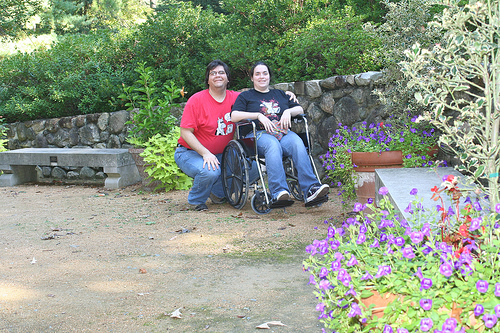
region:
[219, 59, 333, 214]
Woman sitting in a wheelchair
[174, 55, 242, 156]
Woman wearing a red shirt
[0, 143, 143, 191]
A gray stone bench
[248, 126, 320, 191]
A pair of blue jeans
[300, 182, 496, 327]
A bunch of purple flowers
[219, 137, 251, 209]
A round black wheel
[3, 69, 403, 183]
A long stone wall behind the women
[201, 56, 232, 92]
Woman has dark hair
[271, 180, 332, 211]
A pair of sneakers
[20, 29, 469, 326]
this is an outdoor area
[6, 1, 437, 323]
this is in a backyard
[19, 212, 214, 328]
the backyard's ground is dirt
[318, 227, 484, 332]
the flowers are purple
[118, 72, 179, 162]
this is a tall bush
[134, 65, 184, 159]
the tall bush is green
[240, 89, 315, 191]
this person is in a wheelchair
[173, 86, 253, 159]
a person with a red shirt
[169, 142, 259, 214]
a person with blue jeans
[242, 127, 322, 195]
a woman with jeans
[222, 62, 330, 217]
a woman in a wheelchair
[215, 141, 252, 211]
the wheel of a wheelchair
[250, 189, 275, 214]
the wheel of a wheelchair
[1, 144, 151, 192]
a concrete bench near a plant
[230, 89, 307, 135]
a woman with a black shirt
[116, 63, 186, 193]
a pot with green plants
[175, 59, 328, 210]
Two women sit together.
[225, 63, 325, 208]
The woman is in a wheelchair.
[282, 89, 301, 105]
The woman's hand is on the other woman's shoulder.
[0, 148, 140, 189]
The bench is made of stone.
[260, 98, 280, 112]
A graphic is on the shirt.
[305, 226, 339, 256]
The flowers are purple.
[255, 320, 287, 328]
A leaf is on the ground.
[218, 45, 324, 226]
Lady in a wheelchair in a garden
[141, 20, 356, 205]
Man with his arm around a woman in a wheelchair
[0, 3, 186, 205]
Concrete bench in a garden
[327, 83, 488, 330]
Little flowers in a garden near a bench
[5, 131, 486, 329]
Dirt and gravel in a garden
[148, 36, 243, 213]
Man with a red t-shirt and blue jeans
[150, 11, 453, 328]
Two friends in a garden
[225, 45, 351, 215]
Woman sitting in a wheelchair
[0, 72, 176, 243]
Rock wall in a garden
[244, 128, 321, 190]
the jeans are blue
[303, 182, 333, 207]
the shoe is black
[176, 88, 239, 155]
the shirt is red in color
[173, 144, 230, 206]
jeans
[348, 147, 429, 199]
A brown brick colored ceramic pot with a plant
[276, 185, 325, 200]
A pair of black and white shoes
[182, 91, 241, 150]
A red short sleeve shirt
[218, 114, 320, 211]
A metal framed wheel chair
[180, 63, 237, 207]
A person squatting down beside wheel chair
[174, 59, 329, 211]
People in a flower garden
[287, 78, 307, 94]
a stone in a wall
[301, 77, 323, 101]
a stone in a wall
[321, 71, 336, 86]
a stone in a wall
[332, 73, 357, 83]
a stone in a wall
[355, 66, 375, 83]
a stone in a wall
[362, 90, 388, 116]
a stone in a wall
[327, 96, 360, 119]
a stone in a wall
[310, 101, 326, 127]
a stone in a wall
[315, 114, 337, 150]
a stone in a wall